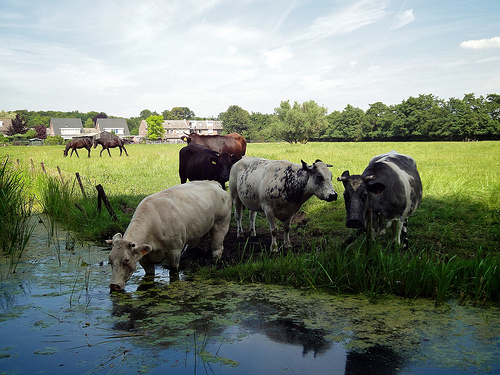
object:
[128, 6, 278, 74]
clouds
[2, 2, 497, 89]
sky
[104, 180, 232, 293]
cow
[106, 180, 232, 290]
cows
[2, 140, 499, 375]
farm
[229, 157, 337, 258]
cow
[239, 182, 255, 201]
black spots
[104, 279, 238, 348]
reflection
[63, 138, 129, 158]
two horses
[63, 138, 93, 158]
horse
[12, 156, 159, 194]
grass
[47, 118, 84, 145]
homes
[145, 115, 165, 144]
tree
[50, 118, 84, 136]
roofs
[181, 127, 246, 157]
cow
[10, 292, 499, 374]
water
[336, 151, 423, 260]
animals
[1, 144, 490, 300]
field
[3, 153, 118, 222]
fence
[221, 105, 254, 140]
trees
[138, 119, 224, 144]
buildings